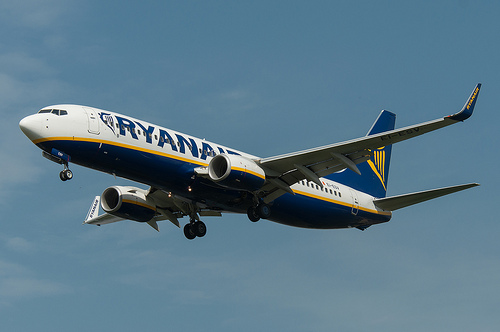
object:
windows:
[60, 109, 68, 115]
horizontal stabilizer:
[371, 181, 480, 212]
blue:
[353, 177, 377, 189]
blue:
[285, 201, 323, 225]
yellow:
[332, 200, 339, 203]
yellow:
[370, 163, 374, 166]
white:
[52, 116, 85, 135]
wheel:
[191, 220, 208, 237]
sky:
[0, 0, 500, 332]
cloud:
[0, 0, 59, 33]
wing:
[197, 82, 482, 203]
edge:
[259, 113, 446, 165]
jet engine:
[207, 151, 266, 192]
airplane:
[14, 81, 483, 243]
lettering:
[113, 114, 242, 161]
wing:
[82, 195, 174, 232]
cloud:
[416, 266, 500, 332]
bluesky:
[1, 0, 498, 329]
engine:
[99, 185, 158, 224]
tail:
[338, 109, 398, 200]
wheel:
[255, 203, 272, 219]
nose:
[18, 106, 57, 129]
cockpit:
[38, 106, 68, 115]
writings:
[174, 133, 200, 158]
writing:
[115, 113, 226, 161]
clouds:
[0, 234, 30, 250]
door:
[85, 106, 101, 134]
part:
[200, 229, 206, 237]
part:
[234, 248, 368, 324]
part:
[200, 224, 205, 228]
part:
[218, 167, 232, 180]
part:
[2, 280, 62, 304]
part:
[4, 162, 38, 184]